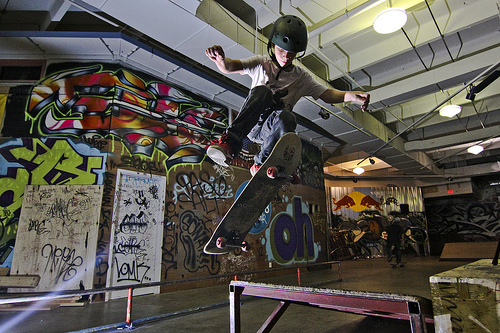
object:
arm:
[304, 72, 349, 104]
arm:
[215, 55, 260, 74]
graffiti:
[28, 200, 143, 301]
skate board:
[203, 132, 303, 254]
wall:
[3, 29, 345, 305]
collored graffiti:
[2, 60, 195, 180]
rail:
[124, 286, 133, 324]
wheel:
[266, 165, 279, 179]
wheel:
[293, 173, 302, 182]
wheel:
[215, 236, 229, 248]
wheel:
[241, 241, 251, 252]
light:
[438, 103, 462, 117]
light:
[371, 9, 408, 35]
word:
[270, 212, 298, 263]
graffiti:
[111, 257, 153, 282]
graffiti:
[267, 193, 322, 263]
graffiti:
[175, 207, 220, 272]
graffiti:
[3, 136, 97, 185]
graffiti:
[24, 216, 59, 238]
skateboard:
[386, 260, 403, 267]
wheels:
[392, 265, 397, 269]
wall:
[328, 181, 426, 246]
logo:
[331, 194, 356, 210]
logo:
[360, 195, 386, 211]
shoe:
[206, 145, 231, 168]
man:
[384, 222, 410, 268]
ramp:
[228, 280, 433, 331]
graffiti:
[176, 167, 231, 210]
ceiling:
[0, 0, 498, 178]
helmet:
[260, 14, 308, 52]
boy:
[204, 15, 370, 176]